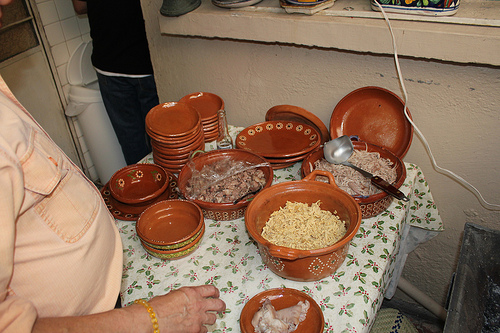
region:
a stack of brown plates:
[143, 102, 205, 173]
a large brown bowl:
[245, 169, 359, 279]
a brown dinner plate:
[239, 288, 321, 330]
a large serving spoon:
[321, 133, 412, 204]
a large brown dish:
[180, 150, 272, 220]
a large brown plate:
[327, 82, 413, 155]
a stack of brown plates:
[236, 119, 321, 166]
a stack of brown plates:
[176, 89, 226, 140]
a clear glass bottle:
[214, 107, 231, 148]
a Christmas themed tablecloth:
[116, 109, 439, 329]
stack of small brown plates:
[138, 95, 214, 185]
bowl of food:
[226, 165, 356, 290]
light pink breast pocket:
[6, 131, 121, 242]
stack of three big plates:
[226, 110, 317, 165]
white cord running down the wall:
[366, 6, 499, 213]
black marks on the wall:
[369, 68, 472, 94]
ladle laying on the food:
[319, 134, 426, 212]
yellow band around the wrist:
[134, 297, 161, 331]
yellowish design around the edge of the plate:
[237, 120, 318, 161]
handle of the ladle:
[362, 172, 414, 204]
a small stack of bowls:
[143, 207, 205, 268]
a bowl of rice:
[243, 183, 351, 279]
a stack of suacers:
[143, 106, 200, 172]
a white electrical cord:
[391, 0, 486, 215]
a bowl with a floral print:
[104, 163, 169, 205]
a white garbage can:
[63, 34, 98, 169]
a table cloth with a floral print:
[326, 219, 401, 332]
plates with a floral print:
[230, 121, 312, 176]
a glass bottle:
[211, 109, 233, 155]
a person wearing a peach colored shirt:
[1, 73, 123, 319]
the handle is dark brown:
[366, 174, 416, 206]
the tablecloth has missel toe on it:
[323, 285, 359, 322]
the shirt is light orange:
[22, 212, 77, 264]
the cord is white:
[386, 31, 413, 83]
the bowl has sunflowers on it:
[127, 166, 145, 183]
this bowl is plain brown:
[331, 79, 419, 145]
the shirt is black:
[106, 19, 131, 56]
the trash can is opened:
[61, 39, 106, 136]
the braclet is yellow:
[128, 292, 170, 331]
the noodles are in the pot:
[261, 186, 341, 266]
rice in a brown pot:
[248, 170, 356, 281]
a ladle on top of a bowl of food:
[325, 135, 407, 202]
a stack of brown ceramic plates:
[148, 94, 205, 177]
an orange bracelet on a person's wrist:
[134, 295, 163, 331]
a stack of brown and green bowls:
[138, 202, 209, 262]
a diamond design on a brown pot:
[257, 250, 354, 277]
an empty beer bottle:
[216, 109, 236, 154]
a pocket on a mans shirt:
[13, 128, 106, 248]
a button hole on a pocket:
[46, 150, 63, 171]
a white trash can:
[53, 41, 129, 183]